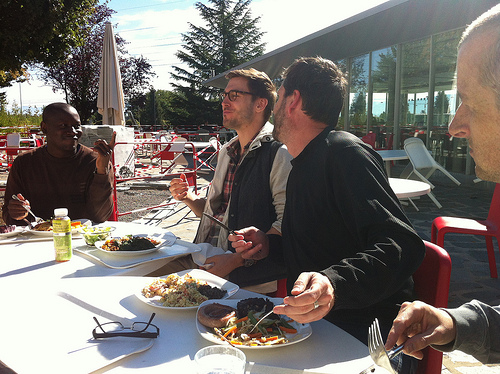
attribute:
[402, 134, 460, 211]
white chair — White 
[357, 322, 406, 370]
fork — silver 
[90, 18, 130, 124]
umbrella — beige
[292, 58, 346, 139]
hair — brown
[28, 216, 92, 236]
white plate — white 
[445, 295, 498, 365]
shirt — grey 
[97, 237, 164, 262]
ceramic plate — white ceramic 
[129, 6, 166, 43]
cloud — white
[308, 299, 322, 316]
ring — Silver 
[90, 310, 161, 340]
glasses — pair 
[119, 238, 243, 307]
plate — white 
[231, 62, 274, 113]
hair — short, brown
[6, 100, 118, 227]
man — eating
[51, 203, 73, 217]
cap — white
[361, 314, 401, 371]
fork — silver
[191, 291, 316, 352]
plate — white ceramic 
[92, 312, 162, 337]
eyeglasses — pair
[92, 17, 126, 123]
umbrella — closed white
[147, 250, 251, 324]
plate — white ceramic 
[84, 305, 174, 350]
eyeglasses — pair 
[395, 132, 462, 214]
chair — leaning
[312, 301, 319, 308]
ring — silver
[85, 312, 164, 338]
glasses — pair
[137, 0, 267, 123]
tree — tall, pine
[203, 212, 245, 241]
knife — silver 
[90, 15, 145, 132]
umbrella — folded up patio table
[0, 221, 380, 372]
table — outdoor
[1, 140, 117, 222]
brown shirt — brown 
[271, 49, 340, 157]
head — man's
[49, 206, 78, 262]
bottle — plastic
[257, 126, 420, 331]
shirt — brown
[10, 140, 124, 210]
shirt — black 